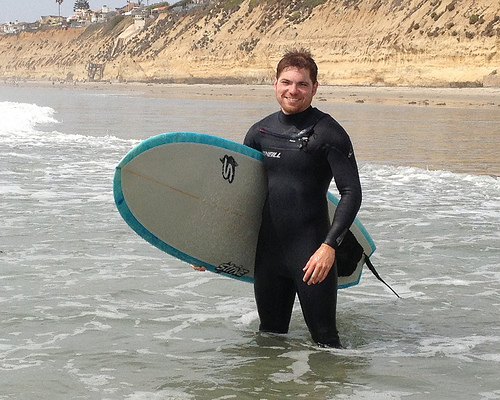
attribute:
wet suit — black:
[236, 105, 356, 329]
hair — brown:
[244, 40, 348, 86]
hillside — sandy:
[2, 1, 499, 87]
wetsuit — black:
[238, 108, 352, 353]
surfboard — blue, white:
[119, 126, 399, 308]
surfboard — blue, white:
[109, 130, 376, 288]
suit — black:
[233, 101, 396, 337]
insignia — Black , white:
[210, 144, 237, 194]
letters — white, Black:
[216, 257, 254, 286]